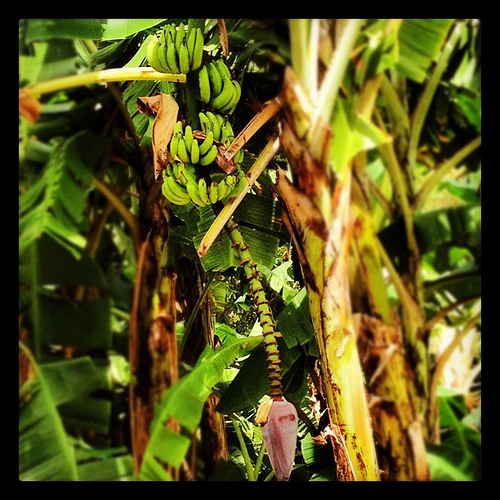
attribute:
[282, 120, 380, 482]
tree stalk — green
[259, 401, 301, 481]
flower — green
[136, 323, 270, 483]
leaf — green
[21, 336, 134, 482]
leaf — green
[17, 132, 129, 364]
leaf — green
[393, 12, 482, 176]
leaf — green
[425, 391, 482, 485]
leaf — green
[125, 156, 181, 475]
tree stalk — green